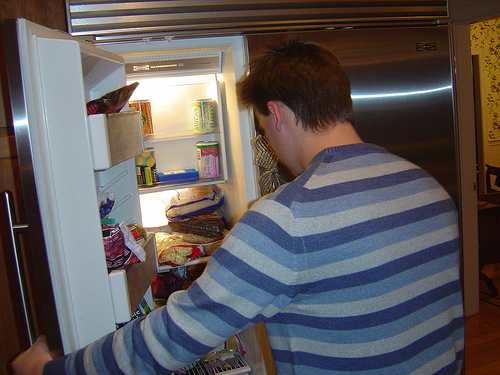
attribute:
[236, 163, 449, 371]
sweater — stripes, blue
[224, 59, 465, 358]
boy — searching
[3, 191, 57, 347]
handle — silver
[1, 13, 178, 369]
fridge door — open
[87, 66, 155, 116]
pack — black, balck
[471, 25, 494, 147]
wall — floral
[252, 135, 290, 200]
ribbon — gold